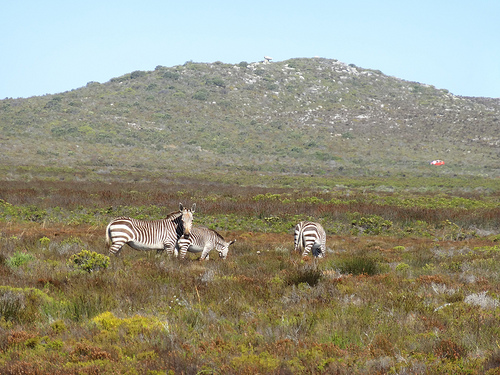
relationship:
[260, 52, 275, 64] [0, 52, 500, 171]
goat on hill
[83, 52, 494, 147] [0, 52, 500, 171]
rocks on hill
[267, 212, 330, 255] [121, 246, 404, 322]
zebras with grass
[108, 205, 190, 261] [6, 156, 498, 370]
zebra in valley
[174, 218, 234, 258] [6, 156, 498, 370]
zebra in valley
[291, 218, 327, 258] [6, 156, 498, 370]
zebra in valley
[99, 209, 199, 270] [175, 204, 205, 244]
zebra holding up head